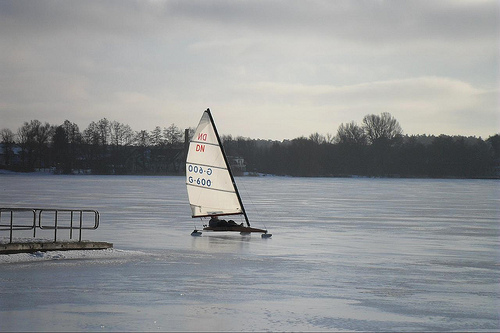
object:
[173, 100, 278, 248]
sailboat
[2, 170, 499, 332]
water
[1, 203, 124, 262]
dock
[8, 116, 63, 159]
trees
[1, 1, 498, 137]
sky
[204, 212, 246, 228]
man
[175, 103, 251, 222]
sail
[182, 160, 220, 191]
letters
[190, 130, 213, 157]
letters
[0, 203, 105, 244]
handrail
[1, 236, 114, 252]
sidewalk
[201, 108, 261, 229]
mast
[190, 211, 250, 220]
boom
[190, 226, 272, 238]
deck